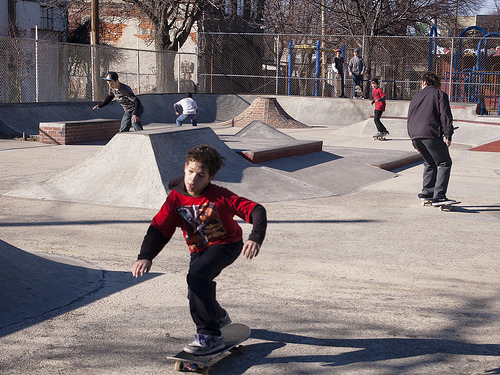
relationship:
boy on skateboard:
[132, 145, 268, 355] [165, 322, 252, 375]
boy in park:
[132, 145, 268, 355] [2, 23, 499, 374]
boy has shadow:
[132, 145, 268, 355] [212, 326, 498, 374]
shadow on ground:
[212, 326, 498, 374] [1, 92, 499, 374]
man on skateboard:
[406, 72, 456, 208] [421, 199, 461, 212]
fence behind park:
[0, 23, 499, 116] [2, 23, 499, 374]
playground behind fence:
[284, 24, 500, 117] [0, 23, 499, 116]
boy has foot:
[132, 145, 268, 355] [183, 333, 225, 355]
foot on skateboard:
[183, 333, 225, 355] [165, 322, 252, 375]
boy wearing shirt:
[132, 145, 268, 355] [149, 184, 258, 255]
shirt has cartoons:
[149, 184, 258, 255] [176, 202, 229, 248]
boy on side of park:
[331, 49, 346, 99] [2, 23, 499, 374]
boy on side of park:
[347, 48, 366, 101] [2, 23, 499, 374]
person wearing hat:
[92, 70, 144, 133] [101, 72, 119, 83]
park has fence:
[2, 23, 499, 374] [0, 23, 499, 116]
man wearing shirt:
[406, 72, 456, 208] [372, 86, 387, 111]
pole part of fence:
[286, 41, 294, 97] [0, 23, 499, 116]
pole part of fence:
[314, 39, 321, 99] [0, 23, 499, 116]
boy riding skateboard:
[132, 145, 268, 355] [165, 322, 252, 375]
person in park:
[92, 70, 144, 133] [2, 23, 499, 374]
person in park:
[172, 92, 202, 125] [2, 23, 499, 374]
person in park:
[368, 76, 389, 136] [2, 23, 499, 374]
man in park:
[406, 72, 456, 208] [2, 23, 499, 374]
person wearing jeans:
[172, 92, 202, 125] [175, 112, 198, 127]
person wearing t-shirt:
[172, 92, 202, 125] [175, 97, 201, 115]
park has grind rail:
[2, 23, 499, 374] [63, 119, 123, 143]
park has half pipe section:
[2, 23, 499, 374] [215, 96, 312, 128]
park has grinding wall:
[2, 23, 499, 374] [235, 140, 324, 165]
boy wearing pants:
[132, 145, 268, 355] [186, 238, 244, 336]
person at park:
[92, 70, 144, 133] [2, 23, 499, 374]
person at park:
[172, 92, 202, 125] [2, 23, 499, 374]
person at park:
[368, 76, 389, 136] [2, 23, 499, 374]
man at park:
[406, 72, 456, 208] [2, 23, 499, 374]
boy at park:
[132, 145, 268, 355] [2, 23, 499, 374]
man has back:
[406, 72, 456, 208] [408, 92, 439, 133]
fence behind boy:
[0, 23, 499, 116] [331, 49, 346, 99]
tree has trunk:
[126, 1, 212, 93] [155, 50, 178, 94]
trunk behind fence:
[155, 50, 178, 94] [0, 23, 499, 116]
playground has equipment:
[284, 24, 500, 117] [444, 25, 500, 114]